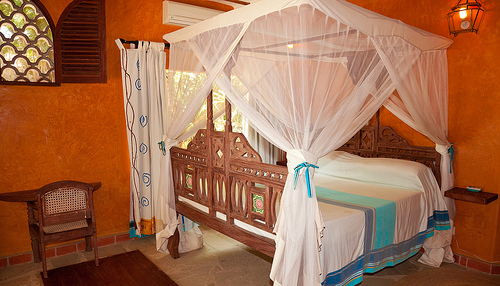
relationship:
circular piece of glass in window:
[10, 52, 48, 103] [26, 101, 76, 160]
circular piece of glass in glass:
[4, 49, 45, 93] [0, 0, 56, 83]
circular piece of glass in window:
[10, 52, 67, 103] [18, 100, 75, 137]